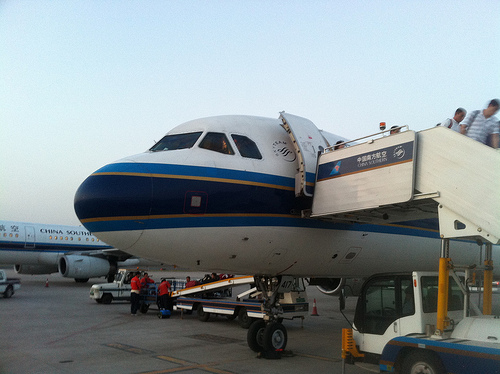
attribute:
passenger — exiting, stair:
[292, 71, 497, 267]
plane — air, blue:
[49, 69, 461, 323]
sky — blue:
[85, 36, 177, 89]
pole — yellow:
[417, 233, 469, 341]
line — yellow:
[148, 340, 194, 374]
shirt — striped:
[466, 120, 491, 155]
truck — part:
[361, 276, 468, 369]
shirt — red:
[154, 275, 173, 300]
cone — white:
[292, 292, 335, 326]